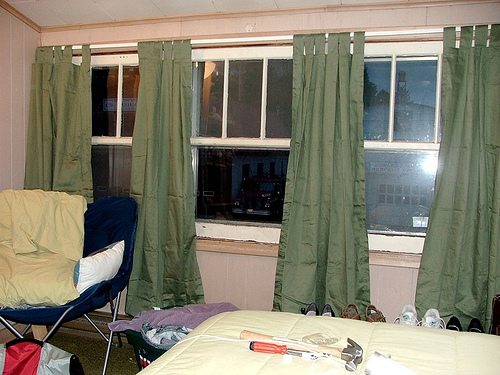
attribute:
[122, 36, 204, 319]
curtain — green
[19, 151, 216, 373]
chairs — blue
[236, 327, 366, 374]
hammer — wooden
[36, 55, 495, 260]
panes — white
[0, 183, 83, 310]
pillow — faded, yellow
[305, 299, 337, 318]
shoes — black, white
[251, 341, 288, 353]
redhandle — red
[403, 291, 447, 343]
shoes — white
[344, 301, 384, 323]
shoes — brown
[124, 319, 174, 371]
laundry basket — green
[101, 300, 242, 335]
clothes — purple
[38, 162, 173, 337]
seat — blue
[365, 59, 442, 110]
sky — blue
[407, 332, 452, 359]
bed sheet — lime white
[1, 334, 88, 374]
bag — red, silver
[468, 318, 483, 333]
black shoe — plain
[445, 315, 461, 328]
black shoe — plain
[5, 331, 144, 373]
carpeting — ugly, green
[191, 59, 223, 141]
window — glass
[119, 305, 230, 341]
towel — light purple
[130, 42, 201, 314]
curtain — drawn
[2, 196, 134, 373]
folding chair — blue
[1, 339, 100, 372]
duffel bag — pink and gray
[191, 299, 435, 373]
comforter — white 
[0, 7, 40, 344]
wall — brown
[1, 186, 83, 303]
blanket — white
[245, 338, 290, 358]
hand — red